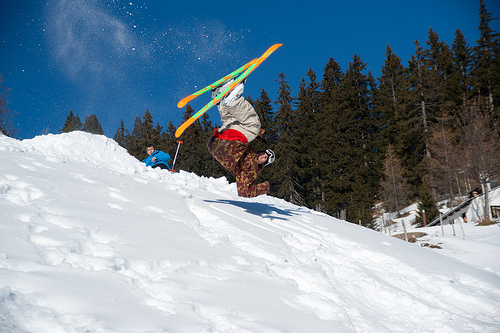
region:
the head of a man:
[246, 146, 279, 172]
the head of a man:
[241, 122, 297, 177]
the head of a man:
[255, 135, 282, 174]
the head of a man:
[246, 135, 288, 162]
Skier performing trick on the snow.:
[174, 43, 284, 198]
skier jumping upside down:
[171, 39, 291, 201]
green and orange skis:
[170, 43, 284, 137]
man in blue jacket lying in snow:
[139, 139, 179, 171]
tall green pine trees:
[280, 5, 493, 205]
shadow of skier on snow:
[196, 195, 306, 226]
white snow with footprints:
[23, 176, 288, 331]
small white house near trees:
[415, 170, 497, 235]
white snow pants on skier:
[215, 79, 262, 140]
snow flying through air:
[43, 8, 240, 82]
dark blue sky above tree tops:
[8, 3, 471, 88]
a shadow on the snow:
[218, 192, 311, 222]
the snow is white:
[188, 244, 269, 286]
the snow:
[168, 256, 255, 329]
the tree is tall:
[306, 81, 392, 208]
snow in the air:
[55, 17, 136, 82]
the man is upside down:
[176, 42, 311, 202]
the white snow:
[136, 219, 242, 298]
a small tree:
[382, 157, 411, 212]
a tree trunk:
[479, 178, 489, 219]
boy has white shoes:
[219, 77, 234, 115]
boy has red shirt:
[187, 131, 257, 143]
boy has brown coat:
[202, 131, 259, 190]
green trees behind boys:
[88, 32, 472, 187]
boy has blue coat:
[147, 149, 170, 168]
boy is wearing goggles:
[249, 146, 283, 173]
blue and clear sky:
[169, 13, 256, 58]